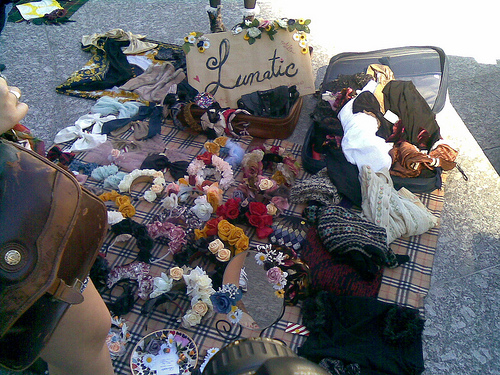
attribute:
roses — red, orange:
[216, 214, 261, 268]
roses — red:
[225, 197, 279, 239]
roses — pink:
[147, 214, 185, 260]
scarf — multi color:
[376, 129, 465, 180]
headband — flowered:
[245, 138, 317, 208]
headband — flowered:
[185, 136, 238, 206]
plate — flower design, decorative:
[123, 319, 208, 375]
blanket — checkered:
[16, 25, 461, 375]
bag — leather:
[2, 138, 108, 375]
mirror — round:
[226, 255, 299, 342]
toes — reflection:
[238, 309, 264, 332]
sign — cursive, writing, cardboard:
[178, 19, 318, 112]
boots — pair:
[204, 323, 338, 375]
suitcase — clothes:
[307, 21, 468, 235]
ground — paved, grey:
[2, 4, 499, 375]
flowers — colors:
[109, 123, 290, 340]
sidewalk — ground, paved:
[7, 9, 228, 154]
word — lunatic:
[204, 45, 301, 101]